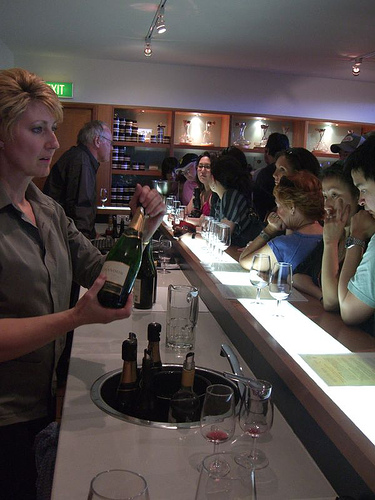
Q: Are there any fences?
A: No, there are no fences.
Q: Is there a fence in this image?
A: No, there are no fences.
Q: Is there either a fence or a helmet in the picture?
A: No, there are no fences or helmets.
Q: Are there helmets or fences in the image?
A: No, there are no fences or helmets.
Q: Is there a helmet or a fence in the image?
A: No, there are no fences or helmets.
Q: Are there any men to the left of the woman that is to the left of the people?
A: Yes, there is a man to the left of the woman.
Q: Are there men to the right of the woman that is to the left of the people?
A: No, the man is to the left of the woman.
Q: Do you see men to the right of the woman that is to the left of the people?
A: No, the man is to the left of the woman.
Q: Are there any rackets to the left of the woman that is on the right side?
A: No, there is a man to the left of the woman.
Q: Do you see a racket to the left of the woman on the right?
A: No, there is a man to the left of the woman.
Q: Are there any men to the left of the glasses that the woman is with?
A: Yes, there is a man to the left of the glasses.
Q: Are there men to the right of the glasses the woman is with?
A: No, the man is to the left of the glasses.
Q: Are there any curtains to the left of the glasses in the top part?
A: No, there is a man to the left of the glasses.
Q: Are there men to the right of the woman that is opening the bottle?
A: Yes, there is a man to the right of the woman.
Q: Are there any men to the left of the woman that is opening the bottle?
A: No, the man is to the right of the woman.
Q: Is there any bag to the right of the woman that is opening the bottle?
A: No, there is a man to the right of the woman.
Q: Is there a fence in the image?
A: No, there are no fences.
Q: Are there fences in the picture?
A: No, there are no fences.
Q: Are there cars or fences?
A: No, there are no fences or cars.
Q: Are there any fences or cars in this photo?
A: No, there are no fences or cars.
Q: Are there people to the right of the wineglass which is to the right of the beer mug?
A: Yes, there are people to the right of the wine glass.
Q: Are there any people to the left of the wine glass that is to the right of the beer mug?
A: No, the people are to the right of the wine glass.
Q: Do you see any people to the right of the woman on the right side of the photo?
A: Yes, there are people to the right of the woman.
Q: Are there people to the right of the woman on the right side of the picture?
A: Yes, there are people to the right of the woman.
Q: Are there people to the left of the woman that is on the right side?
A: No, the people are to the right of the woman.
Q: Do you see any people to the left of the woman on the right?
A: No, the people are to the right of the woman.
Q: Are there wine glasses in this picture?
A: Yes, there is a wine glass.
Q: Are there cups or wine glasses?
A: Yes, there is a wine glass.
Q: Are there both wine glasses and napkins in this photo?
A: No, there is a wine glass but no napkins.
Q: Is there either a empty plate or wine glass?
A: Yes, there is an empty wine glass.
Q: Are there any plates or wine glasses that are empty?
A: Yes, the wine glass is empty.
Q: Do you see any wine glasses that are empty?
A: Yes, there is an empty wine glass.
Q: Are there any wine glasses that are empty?
A: Yes, there is a wine glass that is empty.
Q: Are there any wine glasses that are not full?
A: Yes, there is a empty wine glass.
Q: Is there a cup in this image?
A: No, there are no cups.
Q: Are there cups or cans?
A: No, there are no cups or cans.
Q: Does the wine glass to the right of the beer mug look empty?
A: Yes, the wine glass is empty.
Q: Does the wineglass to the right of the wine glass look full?
A: No, the wine glass is empty.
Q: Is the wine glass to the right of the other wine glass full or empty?
A: The wineglass is empty.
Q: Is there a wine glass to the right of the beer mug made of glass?
A: Yes, there is a wine glass to the right of the beer mug.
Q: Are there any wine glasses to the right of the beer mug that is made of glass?
A: Yes, there is a wine glass to the right of the beer mug.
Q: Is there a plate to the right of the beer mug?
A: No, there is a wine glass to the right of the beer mug.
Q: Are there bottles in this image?
A: Yes, there is a bottle.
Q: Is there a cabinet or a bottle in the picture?
A: Yes, there is a bottle.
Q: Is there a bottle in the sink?
A: Yes, there is a bottle in the sink.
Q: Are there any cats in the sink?
A: No, there is a bottle in the sink.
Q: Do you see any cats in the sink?
A: No, there is a bottle in the sink.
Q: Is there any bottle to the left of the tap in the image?
A: Yes, there is a bottle to the left of the tap.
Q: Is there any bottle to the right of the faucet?
A: No, the bottle is to the left of the faucet.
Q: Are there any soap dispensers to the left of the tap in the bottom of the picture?
A: No, there is a bottle to the left of the tap.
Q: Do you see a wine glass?
A: Yes, there is a wine glass.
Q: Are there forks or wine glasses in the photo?
A: Yes, there is a wine glass.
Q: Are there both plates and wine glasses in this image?
A: No, there is a wine glass but no plates.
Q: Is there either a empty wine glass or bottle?
A: Yes, there is an empty wine glass.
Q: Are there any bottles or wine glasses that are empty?
A: Yes, the wine glass is empty.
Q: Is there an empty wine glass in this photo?
A: Yes, there is an empty wine glass.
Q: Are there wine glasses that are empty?
A: Yes, there is a wine glass that is empty.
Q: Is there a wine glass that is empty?
A: Yes, there is a wine glass that is empty.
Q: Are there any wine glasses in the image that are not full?
A: Yes, there is a empty wine glass.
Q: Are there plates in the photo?
A: No, there are no plates.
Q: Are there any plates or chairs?
A: No, there are no plates or chairs.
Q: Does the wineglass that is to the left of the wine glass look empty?
A: Yes, the wine glass is empty.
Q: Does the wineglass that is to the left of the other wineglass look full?
A: No, the wine glass is empty.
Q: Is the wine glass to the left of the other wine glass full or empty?
A: The wine glass is empty.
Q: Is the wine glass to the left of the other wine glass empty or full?
A: The wine glass is empty.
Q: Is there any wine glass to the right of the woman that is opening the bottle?
A: Yes, there is a wine glass to the right of the woman.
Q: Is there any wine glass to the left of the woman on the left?
A: No, the wine glass is to the right of the woman.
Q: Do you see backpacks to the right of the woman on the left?
A: No, there is a wine glass to the right of the woman.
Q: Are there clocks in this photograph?
A: No, there are no clocks.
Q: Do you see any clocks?
A: No, there are no clocks.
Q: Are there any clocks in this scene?
A: No, there are no clocks.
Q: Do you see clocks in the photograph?
A: No, there are no clocks.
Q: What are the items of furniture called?
A: The pieces of furniture are shelves.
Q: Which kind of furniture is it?
A: The pieces of furniture are shelves.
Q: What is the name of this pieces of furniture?
A: These are shelves.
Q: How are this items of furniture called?
A: These are shelves.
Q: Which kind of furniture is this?
A: These are shelves.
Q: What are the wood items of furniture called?
A: The pieces of furniture are shelves.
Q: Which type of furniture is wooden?
A: The furniture is shelves.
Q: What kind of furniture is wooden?
A: The furniture is shelves.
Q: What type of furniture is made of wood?
A: The furniture is shelves.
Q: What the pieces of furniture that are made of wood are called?
A: The pieces of furniture are shelves.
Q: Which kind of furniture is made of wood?
A: The furniture is shelves.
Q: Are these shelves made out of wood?
A: Yes, the shelves are made of wood.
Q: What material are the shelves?
A: The shelves are made of wood.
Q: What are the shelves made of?
A: The shelves are made of wood.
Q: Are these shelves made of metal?
A: No, the shelves are made of wood.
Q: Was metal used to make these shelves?
A: No, the shelves are made of wood.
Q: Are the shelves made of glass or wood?
A: The shelves are made of wood.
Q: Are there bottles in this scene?
A: Yes, there is a bottle.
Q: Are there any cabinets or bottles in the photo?
A: Yes, there is a bottle.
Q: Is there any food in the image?
A: No, there is no food.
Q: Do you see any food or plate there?
A: No, there are no food or plates.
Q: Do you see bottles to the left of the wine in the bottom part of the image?
A: Yes, there is a bottle to the left of the wine.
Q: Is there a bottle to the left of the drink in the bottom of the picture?
A: Yes, there is a bottle to the left of the wine.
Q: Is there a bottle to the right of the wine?
A: No, the bottle is to the left of the wine.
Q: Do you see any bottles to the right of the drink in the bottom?
A: No, the bottle is to the left of the wine.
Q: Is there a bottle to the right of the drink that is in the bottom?
A: No, the bottle is to the left of the wine.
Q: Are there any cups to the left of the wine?
A: No, there is a bottle to the left of the wine.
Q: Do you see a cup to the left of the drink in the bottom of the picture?
A: No, there is a bottle to the left of the wine.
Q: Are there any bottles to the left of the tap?
A: Yes, there is a bottle to the left of the tap.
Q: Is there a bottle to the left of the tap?
A: Yes, there is a bottle to the left of the tap.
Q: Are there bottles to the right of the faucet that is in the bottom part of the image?
A: No, the bottle is to the left of the tap.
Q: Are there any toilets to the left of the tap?
A: No, there is a bottle to the left of the tap.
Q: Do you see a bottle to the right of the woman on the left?
A: Yes, there is a bottle to the right of the woman.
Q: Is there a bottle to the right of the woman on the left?
A: Yes, there is a bottle to the right of the woman.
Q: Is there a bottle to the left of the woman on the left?
A: No, the bottle is to the right of the woman.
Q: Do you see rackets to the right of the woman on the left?
A: No, there is a bottle to the right of the woman.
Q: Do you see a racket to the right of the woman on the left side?
A: No, there is a bottle to the right of the woman.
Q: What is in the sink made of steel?
A: The bottle is in the sink.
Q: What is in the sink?
A: The bottle is in the sink.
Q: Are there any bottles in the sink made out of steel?
A: Yes, there is a bottle in the sink.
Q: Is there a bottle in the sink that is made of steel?
A: Yes, there is a bottle in the sink.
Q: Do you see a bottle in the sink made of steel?
A: Yes, there is a bottle in the sink.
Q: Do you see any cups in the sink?
A: No, there is a bottle in the sink.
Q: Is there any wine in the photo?
A: Yes, there is wine.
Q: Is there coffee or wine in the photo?
A: Yes, there is wine.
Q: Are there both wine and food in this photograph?
A: No, there is wine but no food.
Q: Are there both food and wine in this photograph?
A: No, there is wine but no food.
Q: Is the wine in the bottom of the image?
A: Yes, the wine is in the bottom of the image.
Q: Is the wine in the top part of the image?
A: No, the wine is in the bottom of the image.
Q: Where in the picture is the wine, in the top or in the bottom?
A: The wine is in the bottom of the image.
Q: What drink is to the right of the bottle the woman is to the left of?
A: The drink is wine.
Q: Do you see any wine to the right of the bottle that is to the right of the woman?
A: Yes, there is wine to the right of the bottle.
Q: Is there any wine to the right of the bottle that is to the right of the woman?
A: Yes, there is wine to the right of the bottle.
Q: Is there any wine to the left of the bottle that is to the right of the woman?
A: No, the wine is to the right of the bottle.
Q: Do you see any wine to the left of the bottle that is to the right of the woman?
A: No, the wine is to the right of the bottle.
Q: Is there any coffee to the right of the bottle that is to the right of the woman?
A: No, there is wine to the right of the bottle.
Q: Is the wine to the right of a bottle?
A: Yes, the wine is to the right of a bottle.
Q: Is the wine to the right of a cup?
A: No, the wine is to the right of a bottle.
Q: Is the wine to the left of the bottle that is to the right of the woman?
A: No, the wine is to the right of the bottle.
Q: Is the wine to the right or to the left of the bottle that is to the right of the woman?
A: The wine is to the right of the bottle.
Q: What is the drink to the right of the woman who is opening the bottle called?
A: The drink is wine.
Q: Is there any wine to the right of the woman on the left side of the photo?
A: Yes, there is wine to the right of the woman.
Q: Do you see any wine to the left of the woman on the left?
A: No, the wine is to the right of the woman.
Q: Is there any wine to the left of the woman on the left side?
A: No, the wine is to the right of the woman.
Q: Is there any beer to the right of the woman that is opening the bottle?
A: No, there is wine to the right of the woman.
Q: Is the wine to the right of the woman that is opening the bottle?
A: Yes, the wine is to the right of the woman.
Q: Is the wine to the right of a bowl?
A: No, the wine is to the right of the woman.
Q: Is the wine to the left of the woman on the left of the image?
A: No, the wine is to the right of the woman.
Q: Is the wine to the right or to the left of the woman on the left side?
A: The wine is to the right of the woman.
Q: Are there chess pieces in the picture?
A: No, there are no chess pieces.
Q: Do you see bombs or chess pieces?
A: No, there are no chess pieces or bombs.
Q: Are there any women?
A: Yes, there is a woman.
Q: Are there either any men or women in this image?
A: Yes, there is a woman.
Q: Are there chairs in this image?
A: No, there are no chairs.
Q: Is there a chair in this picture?
A: No, there are no chairs.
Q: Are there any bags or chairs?
A: No, there are no chairs or bags.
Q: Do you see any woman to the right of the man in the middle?
A: Yes, there is a woman to the right of the man.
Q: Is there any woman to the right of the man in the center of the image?
A: Yes, there is a woman to the right of the man.